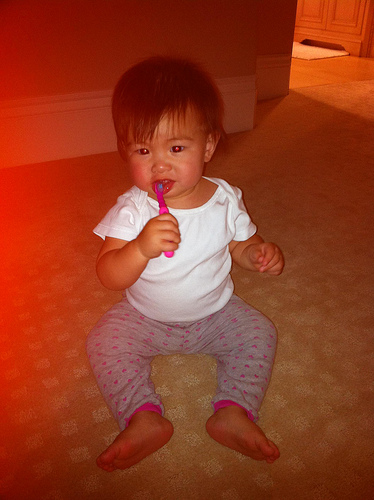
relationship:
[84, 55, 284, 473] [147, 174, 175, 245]
child holding spoon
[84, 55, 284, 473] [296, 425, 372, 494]
child sitting on floor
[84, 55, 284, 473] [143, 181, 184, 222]
child holding toothbrush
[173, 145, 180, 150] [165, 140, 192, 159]
red in child's eye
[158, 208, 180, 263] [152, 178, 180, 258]
handle of toothbrush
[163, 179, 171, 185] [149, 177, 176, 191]
baby teeth in mouth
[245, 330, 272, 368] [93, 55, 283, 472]
hearts on child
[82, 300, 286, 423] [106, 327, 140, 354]
pants has red dots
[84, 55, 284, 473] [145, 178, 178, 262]
child eating spoon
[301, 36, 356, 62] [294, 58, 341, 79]
rug sitting on floor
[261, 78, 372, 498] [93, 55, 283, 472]
floor under child